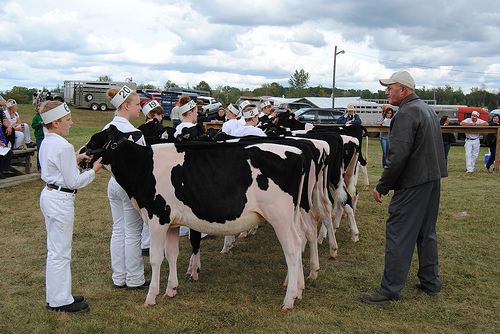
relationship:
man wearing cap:
[360, 69, 447, 301] [377, 68, 417, 88]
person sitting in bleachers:
[9, 94, 33, 151] [2, 117, 37, 186]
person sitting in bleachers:
[0, 96, 12, 143] [2, 117, 37, 186]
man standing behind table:
[458, 109, 488, 176] [366, 120, 484, 135]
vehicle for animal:
[64, 81, 151, 111] [58, 75, 115, 110]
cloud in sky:
[1, 2, 498, 94] [1, 3, 498, 81]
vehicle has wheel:
[64, 81, 151, 111] [84, 93, 94, 102]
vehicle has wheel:
[64, 81, 151, 111] [87, 102, 98, 110]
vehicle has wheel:
[64, 81, 151, 111] [98, 102, 108, 112]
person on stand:
[3, 100, 33, 151] [0, 144, 37, 177]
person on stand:
[0, 92, 15, 174] [0, 144, 37, 177]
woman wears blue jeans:
[375, 106, 396, 168] [377, 129, 390, 168]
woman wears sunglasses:
[375, 106, 396, 168] [383, 110, 391, 115]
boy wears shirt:
[32, 95, 107, 316] [33, 124, 99, 192]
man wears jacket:
[360, 69, 447, 301] [389, 101, 446, 185]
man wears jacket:
[360, 69, 447, 301] [376, 93, 450, 194]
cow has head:
[69, 116, 332, 323] [72, 119, 142, 172]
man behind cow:
[360, 69, 447, 301] [85, 138, 306, 300]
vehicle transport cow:
[64, 81, 151, 111] [85, 138, 306, 300]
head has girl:
[104, 69, 150, 126] [91, 67, 203, 242]